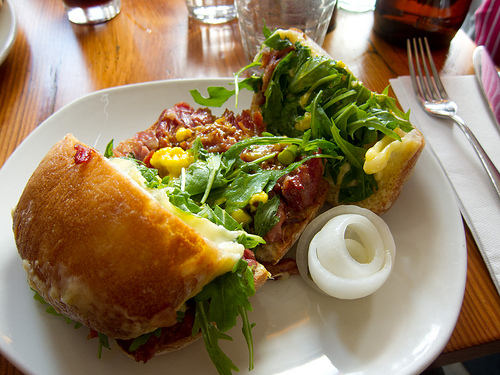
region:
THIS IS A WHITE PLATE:
[0, 68, 472, 372]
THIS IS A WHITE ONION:
[294, 202, 397, 300]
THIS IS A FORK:
[402, 33, 498, 218]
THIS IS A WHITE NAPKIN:
[385, 72, 497, 331]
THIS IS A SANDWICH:
[10, 23, 422, 369]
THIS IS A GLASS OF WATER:
[231, 0, 341, 74]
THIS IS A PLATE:
[0, 0, 16, 63]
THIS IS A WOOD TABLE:
[1, 3, 498, 371]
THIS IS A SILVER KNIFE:
[466, 43, 498, 136]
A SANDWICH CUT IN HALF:
[7, 24, 426, 359]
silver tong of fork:
[403, 38, 420, 102]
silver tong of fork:
[411, 36, 428, 100]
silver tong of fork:
[418, 36, 437, 102]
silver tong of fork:
[421, 34, 446, 98]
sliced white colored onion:
[319, 216, 379, 273]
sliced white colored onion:
[308, 233, 390, 305]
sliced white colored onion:
[296, 204, 396, 301]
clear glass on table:
[233, 2, 334, 67]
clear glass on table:
[188, 0, 234, 25]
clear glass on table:
[65, 3, 118, 22]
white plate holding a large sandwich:
[23, 64, 438, 358]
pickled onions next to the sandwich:
[286, 204, 402, 301]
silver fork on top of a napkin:
[397, 37, 496, 195]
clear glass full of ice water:
[232, 2, 334, 42]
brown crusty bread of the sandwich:
[18, 180, 208, 327]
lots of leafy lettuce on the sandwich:
[295, 66, 383, 169]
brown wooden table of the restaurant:
[19, 32, 159, 90]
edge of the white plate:
[414, 228, 486, 362]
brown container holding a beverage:
[372, 5, 472, 48]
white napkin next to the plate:
[422, 131, 497, 291]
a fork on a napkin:
[402, 36, 498, 199]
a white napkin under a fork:
[390, 73, 499, 292]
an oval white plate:
[0, 75, 465, 370]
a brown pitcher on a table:
[380, 0, 470, 50]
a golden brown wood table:
[0, 0, 495, 371]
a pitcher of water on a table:
[232, 0, 341, 61]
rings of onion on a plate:
[296, 202, 397, 298]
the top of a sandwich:
[14, 136, 241, 342]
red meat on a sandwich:
[133, 102, 321, 236]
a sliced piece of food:
[297, 203, 402, 301]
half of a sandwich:
[6, 127, 274, 366]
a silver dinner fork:
[399, 32, 499, 209]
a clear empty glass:
[234, 2, 341, 76]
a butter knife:
[468, 41, 499, 121]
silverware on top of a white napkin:
[386, 32, 499, 309]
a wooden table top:
[29, 40, 182, 75]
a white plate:
[1, 67, 468, 373]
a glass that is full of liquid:
[367, 0, 497, 50]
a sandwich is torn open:
[11, 27, 431, 362]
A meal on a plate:
[0, 22, 474, 372]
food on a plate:
[0, 20, 469, 374]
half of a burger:
[11, 121, 276, 367]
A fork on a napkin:
[388, 31, 498, 298]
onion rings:
[287, 191, 404, 299]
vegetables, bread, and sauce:
[117, 21, 444, 269]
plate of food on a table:
[0, 0, 497, 370]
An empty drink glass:
[222, 0, 341, 70]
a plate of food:
[4, 20, 472, 373]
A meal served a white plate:
[1, 19, 476, 371]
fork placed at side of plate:
[403, 34, 498, 200]